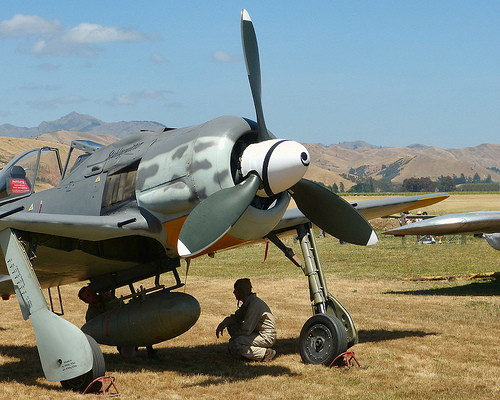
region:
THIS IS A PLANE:
[0, 13, 380, 394]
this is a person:
[205, 234, 310, 394]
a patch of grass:
[325, 372, 397, 399]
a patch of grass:
[390, 314, 447, 391]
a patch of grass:
[342, 240, 401, 301]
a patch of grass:
[420, 360, 445, 385]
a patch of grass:
[399, 243, 449, 288]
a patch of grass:
[434, 318, 461, 399]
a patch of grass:
[207, 251, 254, 288]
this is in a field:
[26, 123, 448, 364]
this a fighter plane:
[31, 131, 321, 360]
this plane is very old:
[16, 151, 291, 341]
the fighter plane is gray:
[48, 143, 384, 362]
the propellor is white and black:
[248, 132, 338, 187]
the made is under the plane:
[158, 262, 367, 397]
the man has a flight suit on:
[225, 285, 284, 367]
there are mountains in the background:
[330, 133, 499, 211]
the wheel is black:
[298, 312, 345, 356]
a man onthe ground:
[218, 278, 280, 363]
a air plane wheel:
[289, 312, 351, 365]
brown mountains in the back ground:
[317, 133, 493, 188]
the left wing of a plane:
[287, 176, 446, 250]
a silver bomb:
[86, 282, 203, 354]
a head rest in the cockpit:
[8, 156, 29, 201]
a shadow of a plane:
[382, 270, 499, 306]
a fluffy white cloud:
[0, 1, 160, 78]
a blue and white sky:
[11, 6, 498, 85]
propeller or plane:
[187, 19, 386, 288]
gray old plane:
[7, 28, 360, 361]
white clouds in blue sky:
[14, 28, 59, 82]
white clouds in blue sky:
[114, 21, 149, 61]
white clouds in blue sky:
[48, 40, 90, 77]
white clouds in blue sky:
[138, 67, 183, 92]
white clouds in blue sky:
[151, 39, 193, 107]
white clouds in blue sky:
[322, 11, 354, 53]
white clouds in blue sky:
[324, 60, 366, 107]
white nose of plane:
[252, 141, 317, 188]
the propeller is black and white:
[161, 18, 438, 329]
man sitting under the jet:
[193, 239, 317, 386]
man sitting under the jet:
[100, 80, 352, 380]